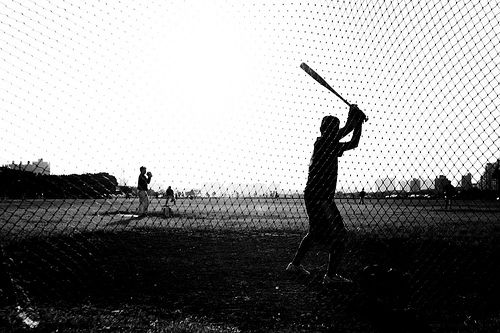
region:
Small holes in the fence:
[6, 211, 67, 259]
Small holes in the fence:
[53, 258, 99, 308]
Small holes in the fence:
[53, 197, 96, 236]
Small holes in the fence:
[74, 151, 111, 197]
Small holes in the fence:
[130, 228, 179, 268]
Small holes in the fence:
[135, 191, 196, 243]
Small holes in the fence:
[151, 146, 195, 187]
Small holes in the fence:
[192, 134, 235, 176]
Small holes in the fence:
[213, 204, 270, 242]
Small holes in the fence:
[215, 228, 267, 265]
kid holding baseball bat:
[265, 58, 378, 299]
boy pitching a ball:
[130, 155, 157, 214]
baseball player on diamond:
[158, 180, 184, 210]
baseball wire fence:
[408, 118, 448, 148]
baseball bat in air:
[290, 51, 354, 107]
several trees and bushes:
[49, 169, 95, 193]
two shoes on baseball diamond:
[286, 260, 360, 297]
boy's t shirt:
[297, 133, 352, 198]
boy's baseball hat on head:
[317, 114, 347, 134]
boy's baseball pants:
[132, 186, 156, 211]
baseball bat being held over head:
[299, 51, 383, 121]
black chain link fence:
[413, 97, 463, 152]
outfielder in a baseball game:
[159, 175, 194, 223]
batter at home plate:
[292, 57, 391, 314]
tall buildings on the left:
[8, 154, 57, 177]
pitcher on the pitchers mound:
[135, 157, 163, 228]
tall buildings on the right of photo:
[408, 165, 498, 191]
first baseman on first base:
[432, 190, 465, 212]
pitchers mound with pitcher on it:
[118, 208, 183, 222]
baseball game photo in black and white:
[38, 39, 418, 251]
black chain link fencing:
[402, 108, 469, 168]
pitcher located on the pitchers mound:
[128, 157, 157, 237]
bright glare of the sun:
[157, 36, 266, 113]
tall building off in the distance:
[406, 165, 481, 194]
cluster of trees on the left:
[10, 174, 78, 196]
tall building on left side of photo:
[23, 153, 60, 168]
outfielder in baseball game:
[161, 182, 187, 208]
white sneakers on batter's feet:
[285, 258, 361, 288]